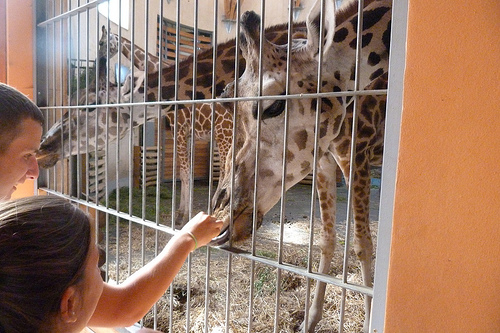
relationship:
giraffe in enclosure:
[207, 2, 384, 249] [43, 2, 390, 330]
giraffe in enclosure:
[32, 12, 374, 331] [43, 2, 390, 330]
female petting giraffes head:
[2, 176, 229, 332] [192, 4, 343, 259]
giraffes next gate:
[66, 32, 356, 223] [149, 22, 216, 70]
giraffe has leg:
[207, 0, 396, 332] [302, 167, 340, 330]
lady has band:
[0, 181, 116, 331] [176, 220, 199, 253]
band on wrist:
[176, 220, 199, 253] [166, 213, 208, 267]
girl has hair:
[2, 185, 115, 331] [6, 77, 33, 124]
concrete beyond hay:
[198, 175, 378, 237] [111, 215, 381, 332]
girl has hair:
[2, 185, 115, 331] [4, 176, 98, 318]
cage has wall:
[29, 5, 409, 328] [387, 4, 499, 331]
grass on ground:
[116, 243, 355, 327] [96, 217, 366, 327]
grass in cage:
[89, 202, 369, 330] [4, 5, 498, 326]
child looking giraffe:
[1, 191, 106, 331] [207, 0, 396, 332]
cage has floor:
[29, 5, 409, 328] [105, 226, 364, 326]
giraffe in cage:
[207, 0, 396, 332] [4, 5, 498, 326]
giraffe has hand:
[207, 0, 396, 332] [175, 203, 226, 253]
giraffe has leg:
[207, 0, 396, 332] [297, 165, 341, 331]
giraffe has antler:
[207, 0, 396, 332] [234, 0, 276, 57]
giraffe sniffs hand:
[207, 0, 396, 332] [172, 205, 220, 252]